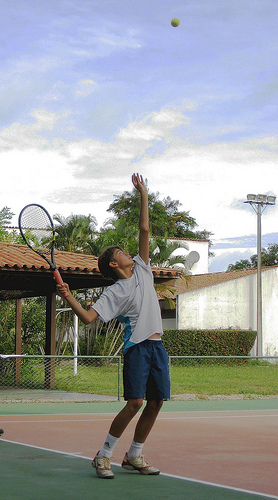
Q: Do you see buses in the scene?
A: No, there are no buses.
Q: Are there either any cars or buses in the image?
A: No, there are no buses or cars.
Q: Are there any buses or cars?
A: No, there are no buses or cars.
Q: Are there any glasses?
A: No, there are no glasses.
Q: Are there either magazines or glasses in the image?
A: No, there are no glasses or magazines.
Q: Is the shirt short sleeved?
A: Yes, the shirt is short sleeved.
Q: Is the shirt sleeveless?
A: No, the shirt is short sleeved.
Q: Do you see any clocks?
A: No, there are no clocks.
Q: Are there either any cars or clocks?
A: No, there are no clocks or cars.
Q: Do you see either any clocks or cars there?
A: No, there are no clocks or cars.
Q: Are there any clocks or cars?
A: No, there are no clocks or cars.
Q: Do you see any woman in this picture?
A: No, there are no women.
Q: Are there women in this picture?
A: No, there are no women.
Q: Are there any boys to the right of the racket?
A: Yes, there is a boy to the right of the racket.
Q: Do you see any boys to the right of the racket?
A: Yes, there is a boy to the right of the racket.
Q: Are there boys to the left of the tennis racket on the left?
A: No, the boy is to the right of the racket.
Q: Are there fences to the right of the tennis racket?
A: No, there is a boy to the right of the tennis racket.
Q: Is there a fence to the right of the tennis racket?
A: No, there is a boy to the right of the tennis racket.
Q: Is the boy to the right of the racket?
A: Yes, the boy is to the right of the racket.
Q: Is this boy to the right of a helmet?
A: No, the boy is to the right of the racket.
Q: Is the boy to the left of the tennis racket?
A: No, the boy is to the right of the tennis racket.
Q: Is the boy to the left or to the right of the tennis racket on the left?
A: The boy is to the right of the racket.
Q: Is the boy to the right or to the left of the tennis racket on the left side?
A: The boy is to the right of the racket.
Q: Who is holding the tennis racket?
A: The boy is holding the tennis racket.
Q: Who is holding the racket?
A: The boy is holding the tennis racket.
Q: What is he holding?
A: The boy is holding the tennis racket.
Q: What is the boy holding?
A: The boy is holding the tennis racket.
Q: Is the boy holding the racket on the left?
A: Yes, the boy is holding the racket.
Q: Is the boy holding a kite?
A: No, the boy is holding the racket.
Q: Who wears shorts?
A: The boy wears shorts.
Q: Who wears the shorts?
A: The boy wears shorts.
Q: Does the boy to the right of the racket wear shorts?
A: Yes, the boy wears shorts.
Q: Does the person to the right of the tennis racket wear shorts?
A: Yes, the boy wears shorts.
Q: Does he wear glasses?
A: No, the boy wears shorts.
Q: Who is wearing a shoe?
A: The boy is wearing a shoe.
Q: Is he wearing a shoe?
A: Yes, the boy is wearing a shoe.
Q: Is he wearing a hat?
A: No, the boy is wearing a shoe.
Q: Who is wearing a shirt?
A: The boy is wearing a shirt.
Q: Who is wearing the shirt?
A: The boy is wearing a shirt.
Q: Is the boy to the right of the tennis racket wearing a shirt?
A: Yes, the boy is wearing a shirt.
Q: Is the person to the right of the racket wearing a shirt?
A: Yes, the boy is wearing a shirt.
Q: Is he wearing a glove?
A: No, the boy is wearing a shirt.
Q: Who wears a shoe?
A: The boy wears a shoe.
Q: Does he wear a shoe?
A: Yes, the boy wears a shoe.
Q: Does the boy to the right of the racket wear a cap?
A: No, the boy wears a shoe.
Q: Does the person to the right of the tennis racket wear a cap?
A: No, the boy wears a shoe.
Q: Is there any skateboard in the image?
A: No, there are no skateboards.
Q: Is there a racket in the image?
A: Yes, there is a racket.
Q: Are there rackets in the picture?
A: Yes, there is a racket.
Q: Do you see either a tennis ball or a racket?
A: Yes, there is a racket.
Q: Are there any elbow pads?
A: No, there are no elbow pads.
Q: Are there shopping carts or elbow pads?
A: No, there are no elbow pads or shopping carts.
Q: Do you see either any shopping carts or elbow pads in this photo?
A: No, there are no elbow pads or shopping carts.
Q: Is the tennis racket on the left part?
A: Yes, the tennis racket is on the left of the image.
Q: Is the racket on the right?
A: No, the racket is on the left of the image.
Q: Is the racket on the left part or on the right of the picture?
A: The racket is on the left of the image.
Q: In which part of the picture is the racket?
A: The racket is on the left of the image.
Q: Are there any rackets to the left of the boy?
A: Yes, there is a racket to the left of the boy.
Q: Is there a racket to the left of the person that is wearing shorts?
A: Yes, there is a racket to the left of the boy.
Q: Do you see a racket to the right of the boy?
A: No, the racket is to the left of the boy.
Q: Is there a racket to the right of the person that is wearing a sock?
A: No, the racket is to the left of the boy.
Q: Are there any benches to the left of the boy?
A: No, there is a racket to the left of the boy.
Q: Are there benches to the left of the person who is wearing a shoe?
A: No, there is a racket to the left of the boy.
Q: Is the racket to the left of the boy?
A: Yes, the racket is to the left of the boy.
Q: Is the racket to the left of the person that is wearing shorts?
A: Yes, the racket is to the left of the boy.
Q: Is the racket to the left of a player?
A: No, the racket is to the left of the boy.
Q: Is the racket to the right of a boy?
A: No, the racket is to the left of a boy.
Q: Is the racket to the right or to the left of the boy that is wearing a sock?
A: The racket is to the left of the boy.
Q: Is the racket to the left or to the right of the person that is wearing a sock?
A: The racket is to the left of the boy.